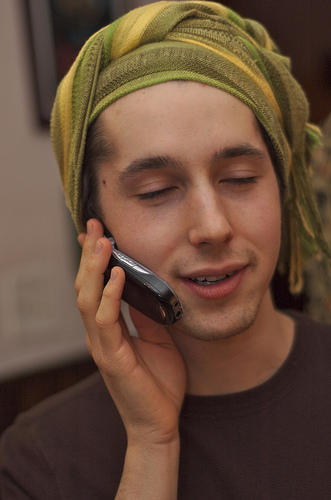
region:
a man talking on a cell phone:
[0, 1, 329, 498]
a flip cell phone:
[81, 216, 185, 328]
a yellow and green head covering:
[45, 0, 319, 294]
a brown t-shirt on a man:
[1, 312, 320, 498]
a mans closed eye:
[130, 179, 182, 203]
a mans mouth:
[172, 259, 250, 298]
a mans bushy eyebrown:
[121, 156, 177, 176]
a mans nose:
[190, 173, 231, 244]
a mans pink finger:
[95, 265, 125, 351]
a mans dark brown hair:
[83, 108, 114, 224]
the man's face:
[77, 68, 281, 338]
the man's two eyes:
[132, 158, 261, 202]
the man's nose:
[188, 166, 233, 249]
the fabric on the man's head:
[49, 2, 327, 294]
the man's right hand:
[73, 218, 186, 434]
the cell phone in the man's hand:
[84, 217, 181, 324]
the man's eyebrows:
[107, 140, 270, 182]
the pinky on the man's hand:
[95, 265, 136, 355]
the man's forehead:
[106, 76, 266, 148]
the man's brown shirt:
[4, 312, 326, 495]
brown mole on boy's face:
[84, 169, 117, 190]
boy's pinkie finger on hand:
[93, 278, 124, 344]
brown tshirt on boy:
[246, 431, 296, 482]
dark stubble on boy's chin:
[195, 311, 240, 347]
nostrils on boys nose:
[196, 222, 248, 244]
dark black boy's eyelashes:
[130, 189, 184, 206]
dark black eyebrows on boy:
[216, 132, 262, 163]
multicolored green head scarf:
[161, 37, 205, 70]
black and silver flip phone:
[124, 256, 173, 320]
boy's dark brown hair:
[85, 142, 109, 194]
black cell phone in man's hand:
[101, 232, 182, 326]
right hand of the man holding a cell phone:
[70, 216, 187, 498]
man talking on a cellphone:
[6, 2, 326, 493]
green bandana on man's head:
[47, 0, 321, 258]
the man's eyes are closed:
[128, 169, 269, 198]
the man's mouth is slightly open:
[178, 258, 252, 296]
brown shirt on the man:
[1, 308, 329, 499]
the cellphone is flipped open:
[99, 232, 184, 322]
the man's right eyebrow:
[118, 152, 186, 176]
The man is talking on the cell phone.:
[3, 0, 324, 493]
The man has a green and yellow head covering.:
[49, 12, 316, 326]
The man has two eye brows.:
[112, 138, 266, 176]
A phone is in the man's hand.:
[63, 214, 193, 420]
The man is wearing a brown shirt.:
[0, 293, 330, 494]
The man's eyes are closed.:
[125, 154, 266, 203]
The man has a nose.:
[175, 170, 228, 241]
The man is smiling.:
[170, 247, 252, 305]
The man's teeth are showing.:
[184, 267, 234, 282]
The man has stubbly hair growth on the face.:
[161, 238, 273, 346]